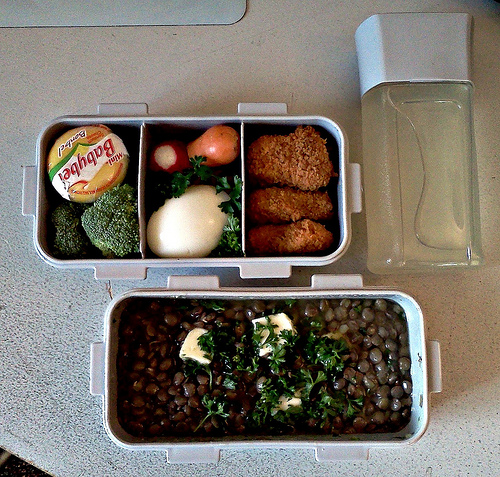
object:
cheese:
[45, 122, 130, 204]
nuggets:
[246, 218, 335, 255]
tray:
[35, 117, 141, 264]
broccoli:
[80, 182, 141, 258]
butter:
[179, 327, 215, 364]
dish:
[76, 297, 134, 426]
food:
[46, 121, 338, 258]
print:
[56, 138, 117, 185]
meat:
[247, 125, 338, 192]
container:
[21, 100, 364, 279]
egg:
[146, 184, 233, 258]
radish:
[145, 138, 192, 177]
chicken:
[245, 185, 335, 225]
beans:
[158, 354, 175, 372]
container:
[351, 9, 488, 275]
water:
[360, 82, 484, 275]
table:
[0, 0, 500, 477]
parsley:
[215, 175, 244, 215]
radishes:
[185, 126, 240, 168]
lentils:
[174, 394, 188, 407]